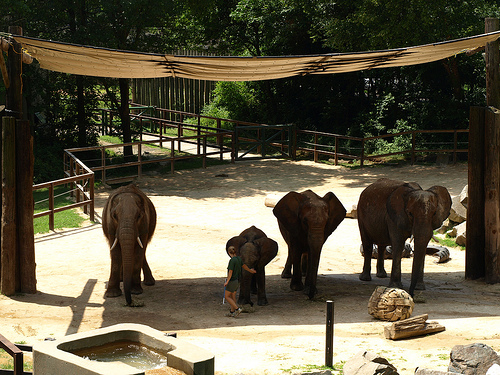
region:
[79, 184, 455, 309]
The elephants are gray.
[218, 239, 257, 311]
The man has a green shirt.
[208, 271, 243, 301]
He has tan pants.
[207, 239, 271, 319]
He is next to the elephant.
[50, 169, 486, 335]
They are in the shade.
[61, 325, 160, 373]
The water is in the pool.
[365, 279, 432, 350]
The wood is on the floor.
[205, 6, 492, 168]
The trees are leafy.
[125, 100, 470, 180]
The fence is short.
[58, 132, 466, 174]
The fence is wooden.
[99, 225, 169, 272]
white tusks on elephant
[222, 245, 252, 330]
man standing by elephant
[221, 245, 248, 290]
person in green shirt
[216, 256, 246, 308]
person in gray shorts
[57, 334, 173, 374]
dirty water cement pond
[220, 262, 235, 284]
left arm on person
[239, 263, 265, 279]
right arm on person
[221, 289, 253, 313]
left leg on person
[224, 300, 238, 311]
right leg on person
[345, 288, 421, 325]
big rock on ground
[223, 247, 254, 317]
woman in green touching an elephant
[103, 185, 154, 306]
elephant standing in the shade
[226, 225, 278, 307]
baby elephant standing by a big elephant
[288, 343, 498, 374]
rocks in front of the elephants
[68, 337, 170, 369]
water for the elephants to drink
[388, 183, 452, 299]
head of a big elephant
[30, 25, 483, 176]
trees behind the elephants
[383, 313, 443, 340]
piece of wood in front of the elephants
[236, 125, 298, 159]
gate to the elephant's place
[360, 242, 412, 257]
old tire for the elephants to play with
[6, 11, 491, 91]
tan fabric canopy between two poles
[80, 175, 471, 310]
elephants in shade of canopy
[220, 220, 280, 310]
zookeeper touching young elephant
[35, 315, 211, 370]
square cement container filled with water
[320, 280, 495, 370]
short black pole near rocks, log and woven basket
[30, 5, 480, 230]
green trees between brown railing and fence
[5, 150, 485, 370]
dry tan ground of enclosure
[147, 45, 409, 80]
pole and gathers along canopy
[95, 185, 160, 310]
ears against side of head behind tusks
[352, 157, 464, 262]
rocks and curved rubber behind elephant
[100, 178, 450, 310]
four elephants in a confined area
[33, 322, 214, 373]
drinking trough full of water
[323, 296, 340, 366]
pole in the ground in front of the elephants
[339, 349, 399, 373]
rock on the ground next to a pole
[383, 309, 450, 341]
log laying on the ground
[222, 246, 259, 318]
person wearing shorts in front of the baby elephant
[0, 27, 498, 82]
canopy roof above the elephants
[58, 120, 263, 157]
pathway behind a closed wood gate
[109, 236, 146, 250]
two pointy white tusks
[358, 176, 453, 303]
largest elephant in the scene